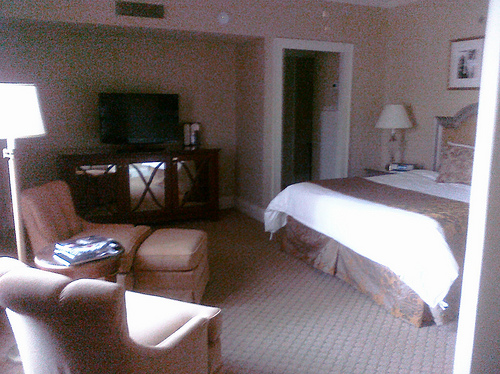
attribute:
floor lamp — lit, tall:
[0, 82, 47, 264]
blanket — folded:
[263, 181, 461, 308]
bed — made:
[263, 103, 478, 328]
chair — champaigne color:
[18, 179, 151, 291]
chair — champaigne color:
[1, 255, 225, 374]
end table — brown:
[33, 243, 122, 285]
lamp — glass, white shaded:
[373, 103, 414, 168]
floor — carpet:
[0, 206, 459, 374]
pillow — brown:
[434, 140, 475, 186]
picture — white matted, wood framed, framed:
[445, 36, 486, 92]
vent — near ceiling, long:
[114, 1, 166, 20]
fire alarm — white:
[215, 10, 230, 25]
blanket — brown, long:
[279, 175, 469, 327]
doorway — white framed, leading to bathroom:
[267, 36, 355, 202]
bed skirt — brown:
[280, 215, 434, 328]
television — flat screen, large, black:
[96, 91, 181, 153]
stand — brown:
[55, 147, 221, 224]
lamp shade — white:
[374, 104, 415, 130]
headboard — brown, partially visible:
[432, 102, 479, 171]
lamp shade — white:
[0, 82, 47, 140]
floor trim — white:
[218, 192, 266, 226]